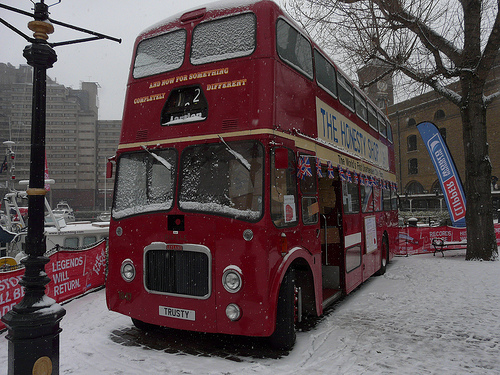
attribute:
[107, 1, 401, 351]
bus — red, double decker, parked, tall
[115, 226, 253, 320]
lights — round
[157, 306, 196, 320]
sign — small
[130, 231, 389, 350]
tires — black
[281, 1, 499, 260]
tree — bare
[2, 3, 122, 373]
post — black, gold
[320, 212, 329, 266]
bar — silver